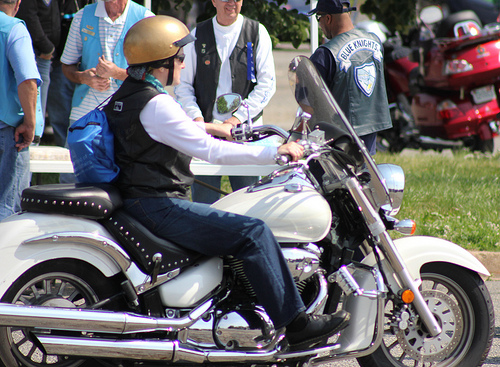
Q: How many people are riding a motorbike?
A: One.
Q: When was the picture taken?
A: Daytime.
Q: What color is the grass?
A: Green.